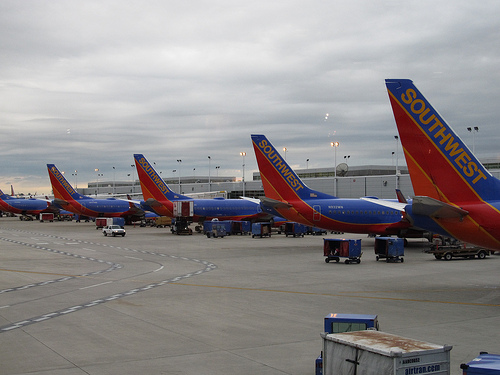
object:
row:
[0, 79, 500, 260]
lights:
[333, 140, 341, 148]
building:
[75, 173, 238, 199]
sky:
[0, 0, 500, 196]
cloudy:
[0, 0, 500, 198]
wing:
[381, 75, 500, 206]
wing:
[128, 151, 194, 205]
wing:
[44, 161, 94, 204]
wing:
[247, 132, 342, 205]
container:
[318, 326, 455, 374]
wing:
[0, 187, 9, 202]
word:
[256, 134, 305, 193]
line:
[13, 317, 32, 324]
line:
[81, 296, 103, 312]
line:
[76, 277, 116, 289]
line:
[151, 258, 168, 276]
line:
[56, 275, 76, 283]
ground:
[0, 212, 500, 374]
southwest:
[400, 86, 492, 186]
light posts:
[331, 147, 343, 198]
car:
[102, 224, 129, 238]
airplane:
[383, 77, 500, 261]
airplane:
[247, 132, 413, 239]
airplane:
[130, 151, 291, 236]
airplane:
[0, 187, 72, 224]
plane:
[45, 161, 148, 226]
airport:
[0, 125, 500, 374]